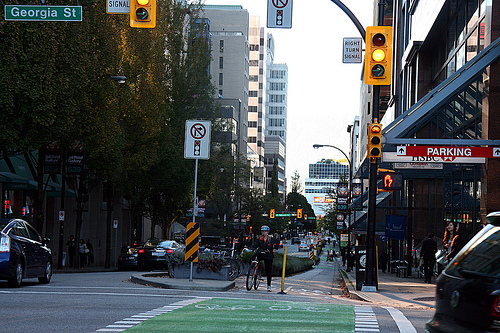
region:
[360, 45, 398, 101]
part of a traffic light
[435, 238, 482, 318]
back of a car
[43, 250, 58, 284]
front wheel of a car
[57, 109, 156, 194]
part of green tree branches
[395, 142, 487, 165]
part of a red banner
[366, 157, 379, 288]
part of a black post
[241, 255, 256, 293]
front wheel of a bicycle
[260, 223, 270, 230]
part of a helmet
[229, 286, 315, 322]
a green part on the road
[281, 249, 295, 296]
part of a yellow post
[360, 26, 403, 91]
yellow stoplight with three lights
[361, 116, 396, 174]
yellow stoplight with three lights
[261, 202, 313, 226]
yellow stoplight with three lights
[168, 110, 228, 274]
city street sign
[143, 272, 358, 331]
crosswalk in busy city street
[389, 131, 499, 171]
red and white parking sign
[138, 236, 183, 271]
black compact car stopped in city street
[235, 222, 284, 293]
woman riding bike on city street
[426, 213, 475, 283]
two ladies waiting on street corner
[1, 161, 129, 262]
store fronts on city streets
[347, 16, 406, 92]
Yellow light on traffic signal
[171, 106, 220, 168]
No right turn on red traffic sign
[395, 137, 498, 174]
Red and white parking entrance sign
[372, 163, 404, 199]
Do not walk signal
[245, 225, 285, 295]
Person stopped on bike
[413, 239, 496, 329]
Back of black car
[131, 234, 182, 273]
Car with brake lights on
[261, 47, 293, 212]
High rise building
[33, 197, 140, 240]
No parking signs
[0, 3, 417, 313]
Georgia St intersection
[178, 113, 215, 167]
part of a white road sign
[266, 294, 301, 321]
green part on the road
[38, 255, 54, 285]
front wheel of a car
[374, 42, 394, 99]
part of a traffic light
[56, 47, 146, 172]
part of some tree branches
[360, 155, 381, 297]
part of a metal black post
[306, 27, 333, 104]
part of the sky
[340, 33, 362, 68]
Right turn signal sign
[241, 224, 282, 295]
a bicyclist waits for the light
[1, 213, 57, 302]
a car driving in the street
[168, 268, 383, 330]
green crosswalk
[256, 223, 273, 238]
an individual wearing a blue helmet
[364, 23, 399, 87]
a traffic signal giving a yellow indicator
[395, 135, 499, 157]
a red and white parking sign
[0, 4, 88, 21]
a green and white sign that says Georgia St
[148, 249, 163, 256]
a white license plate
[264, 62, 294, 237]
a tall white building